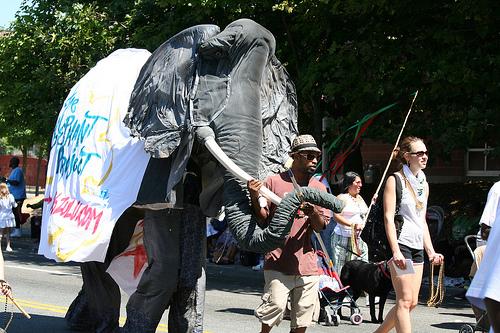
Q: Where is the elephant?
A: Behind the man.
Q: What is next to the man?
A: A woman.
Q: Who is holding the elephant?
A: The man.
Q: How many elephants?
A: 1.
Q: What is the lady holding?
A: Paper.